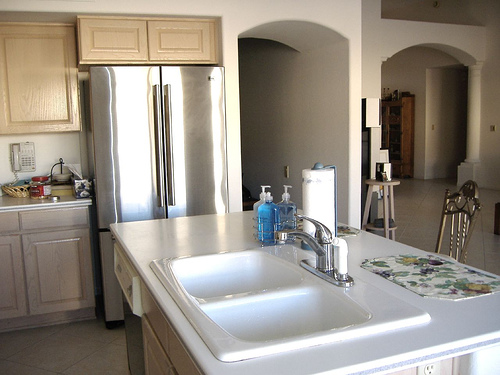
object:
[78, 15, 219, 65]
cabinet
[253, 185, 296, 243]
bottles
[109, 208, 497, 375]
counter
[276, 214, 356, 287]
faucet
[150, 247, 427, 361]
sink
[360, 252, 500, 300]
placemat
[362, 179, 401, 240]
barstool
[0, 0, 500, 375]
room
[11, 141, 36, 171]
phone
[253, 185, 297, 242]
soap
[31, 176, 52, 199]
jar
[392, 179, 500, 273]
ground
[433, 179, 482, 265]
chair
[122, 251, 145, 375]
dishwasher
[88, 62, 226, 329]
fridge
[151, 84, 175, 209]
handles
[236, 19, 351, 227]
doorway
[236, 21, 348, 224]
hallway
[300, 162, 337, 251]
dispenser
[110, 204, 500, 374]
kitchen counter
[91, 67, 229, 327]
refrigerator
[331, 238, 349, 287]
sprayer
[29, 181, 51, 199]
nuts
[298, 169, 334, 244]
towels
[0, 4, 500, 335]
wall